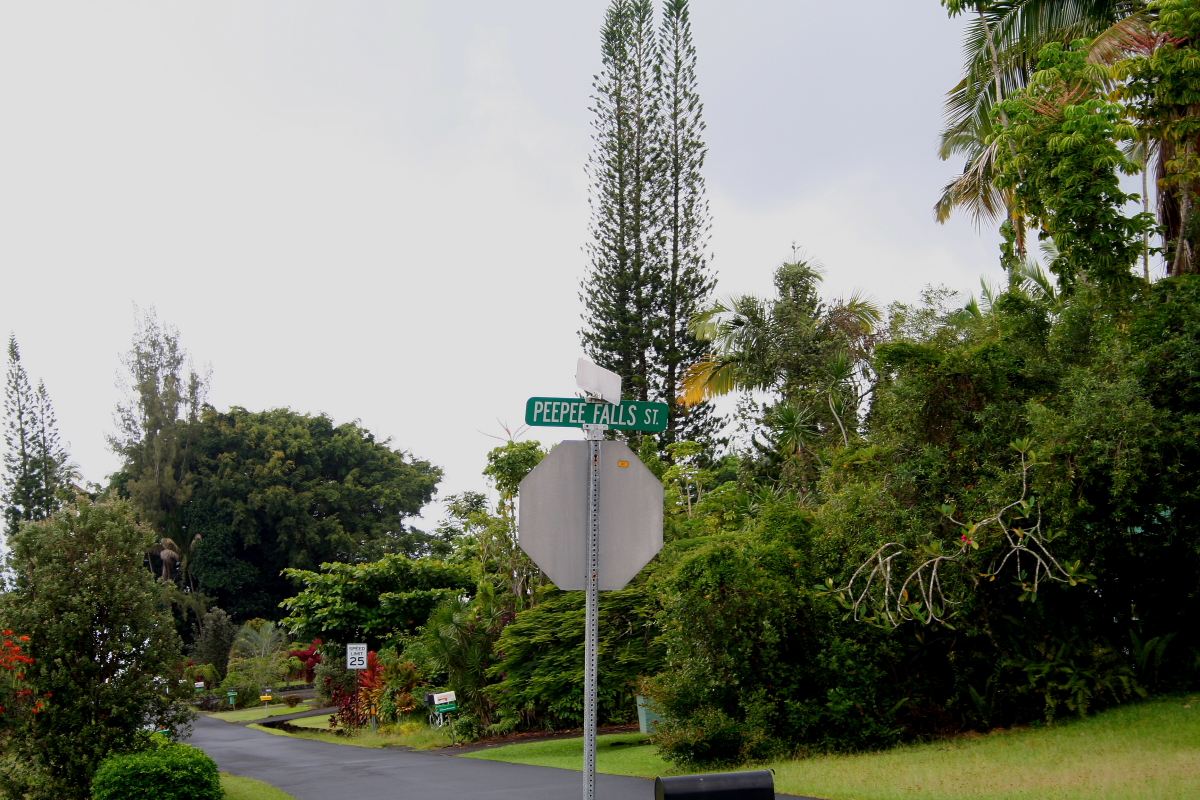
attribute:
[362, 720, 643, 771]
lawn — green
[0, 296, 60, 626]
bush — tall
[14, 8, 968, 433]
sky — grey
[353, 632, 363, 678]
sign — black and white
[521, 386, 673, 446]
sign — green and white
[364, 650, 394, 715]
flowers — red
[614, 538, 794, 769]
bush — green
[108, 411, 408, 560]
leaves — green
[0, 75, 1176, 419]
sky — cloudy